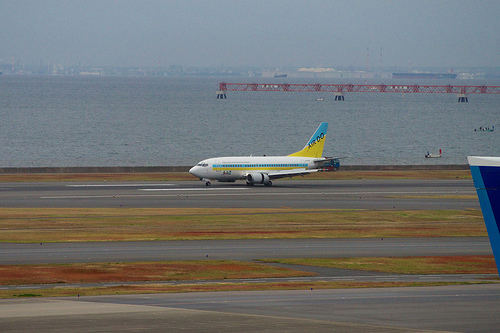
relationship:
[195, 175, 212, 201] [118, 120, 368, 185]
tire on front of airplane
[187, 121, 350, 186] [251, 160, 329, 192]
airplane has a wing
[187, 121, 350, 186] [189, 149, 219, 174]
airplane has a windshield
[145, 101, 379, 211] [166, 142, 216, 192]
airplane has a nose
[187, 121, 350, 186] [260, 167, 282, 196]
airplane has a wheel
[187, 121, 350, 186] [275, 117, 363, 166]
airplane has a tail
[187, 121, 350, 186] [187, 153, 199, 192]
airplane has a nose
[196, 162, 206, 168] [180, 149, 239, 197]
cockpit window near cockpit area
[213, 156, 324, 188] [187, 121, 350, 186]
passenger window on side of airplane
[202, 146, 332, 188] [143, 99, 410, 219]
stripes on side of plane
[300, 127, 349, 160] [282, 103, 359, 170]
word on tail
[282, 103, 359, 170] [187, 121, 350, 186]
tail on airplane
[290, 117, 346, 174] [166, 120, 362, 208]
tail on plane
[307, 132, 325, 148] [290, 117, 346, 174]
word on tail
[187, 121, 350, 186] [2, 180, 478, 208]
airplane on airport runway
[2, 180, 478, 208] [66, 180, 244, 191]
airport runway with lines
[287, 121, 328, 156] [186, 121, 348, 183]
tail fin on air plane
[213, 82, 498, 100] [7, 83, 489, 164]
structure over ocean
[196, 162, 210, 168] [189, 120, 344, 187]
cockpit window on plane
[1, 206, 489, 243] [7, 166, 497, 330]
grass by airplane runway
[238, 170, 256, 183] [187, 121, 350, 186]
propeller on airplane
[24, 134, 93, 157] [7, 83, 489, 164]
ripples on ocean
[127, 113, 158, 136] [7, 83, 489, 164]
wave on ocean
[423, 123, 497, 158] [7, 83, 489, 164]
things floating in ocean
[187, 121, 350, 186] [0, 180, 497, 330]
airplane on airplane runway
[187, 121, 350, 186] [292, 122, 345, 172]
airplane with tail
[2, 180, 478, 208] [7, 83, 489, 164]
airport runway beside ocean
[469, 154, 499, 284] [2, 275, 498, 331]
tail on runway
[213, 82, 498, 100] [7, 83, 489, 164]
structure in ocean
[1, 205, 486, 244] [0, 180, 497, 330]
grass on airplane runway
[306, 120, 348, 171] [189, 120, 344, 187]
tail wing of plane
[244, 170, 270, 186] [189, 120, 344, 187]
engine on left side plane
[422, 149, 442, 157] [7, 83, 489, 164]
bouy in ocean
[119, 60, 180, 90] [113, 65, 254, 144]
buildings behind water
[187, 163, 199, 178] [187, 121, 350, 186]
nose of airplane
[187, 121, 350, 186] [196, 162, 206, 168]
airplane with cockpit window